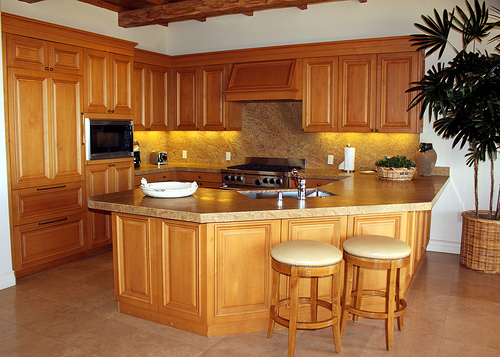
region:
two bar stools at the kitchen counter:
[262, 233, 418, 355]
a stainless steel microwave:
[83, 113, 134, 160]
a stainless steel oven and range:
[218, 153, 304, 188]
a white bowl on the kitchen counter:
[137, 175, 199, 199]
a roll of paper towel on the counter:
[337, 142, 356, 172]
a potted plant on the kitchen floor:
[405, 3, 498, 272]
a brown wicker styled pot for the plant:
[459, 205, 499, 273]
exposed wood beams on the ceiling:
[20, 0, 382, 30]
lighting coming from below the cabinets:
[133, 125, 238, 141]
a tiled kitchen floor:
[0, 248, 497, 355]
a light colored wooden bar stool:
[268, 240, 343, 355]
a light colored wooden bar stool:
[341, 233, 412, 350]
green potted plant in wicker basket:
[403, 0, 498, 274]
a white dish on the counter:
[139, 175, 198, 196]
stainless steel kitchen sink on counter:
[236, 186, 337, 199]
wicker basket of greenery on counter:
[373, 156, 416, 180]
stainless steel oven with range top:
[219, 155, 306, 190]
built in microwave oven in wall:
[85, 115, 135, 161]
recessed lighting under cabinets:
[130, 128, 418, 144]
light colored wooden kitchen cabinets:
[0, 9, 425, 279]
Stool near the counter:
[338, 228, 425, 355]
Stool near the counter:
[262, 231, 349, 355]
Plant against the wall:
[402, 5, 497, 280]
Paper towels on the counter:
[330, 136, 360, 176]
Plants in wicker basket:
[360, 145, 420, 185]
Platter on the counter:
[125, 170, 200, 200]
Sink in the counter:
[237, 180, 327, 205]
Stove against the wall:
[215, 148, 308, 193]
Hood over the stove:
[218, 51, 315, 117]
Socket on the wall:
[216, 142, 236, 172]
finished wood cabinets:
[302, 47, 422, 134]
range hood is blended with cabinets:
[220, 58, 302, 103]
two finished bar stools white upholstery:
[264, 235, 414, 352]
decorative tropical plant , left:
[441, 8, 497, 275]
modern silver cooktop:
[221, 153, 292, 188]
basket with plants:
[373, 154, 418, 181]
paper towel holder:
[343, 142, 357, 174]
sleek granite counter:
[186, 198, 381, 219]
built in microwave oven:
[86, 119, 136, 157]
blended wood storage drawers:
[9, 182, 91, 263]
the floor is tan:
[35, 286, 82, 336]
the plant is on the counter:
[372, 152, 419, 183]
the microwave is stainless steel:
[84, 115, 136, 162]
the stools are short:
[255, 230, 427, 347]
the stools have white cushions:
[257, 232, 415, 353]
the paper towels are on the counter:
[340, 137, 357, 175]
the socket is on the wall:
[322, 147, 337, 167]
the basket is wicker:
[458, 207, 494, 272]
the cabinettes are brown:
[299, 52, 419, 134]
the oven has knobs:
[220, 168, 245, 185]